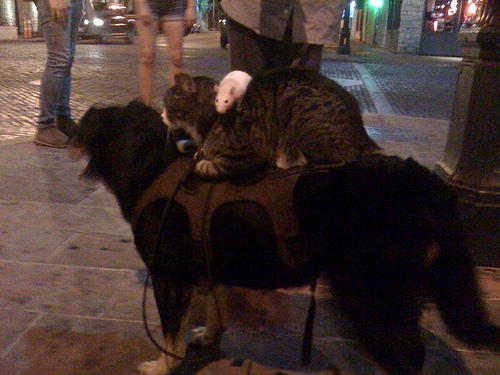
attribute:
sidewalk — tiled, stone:
[32, 269, 324, 374]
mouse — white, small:
[215, 70, 253, 113]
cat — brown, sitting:
[161, 82, 368, 172]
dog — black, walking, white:
[98, 128, 471, 309]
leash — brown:
[144, 175, 176, 348]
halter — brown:
[153, 177, 283, 215]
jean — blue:
[34, 27, 67, 119]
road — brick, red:
[345, 56, 451, 102]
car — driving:
[80, 4, 140, 40]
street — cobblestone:
[56, 35, 115, 89]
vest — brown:
[156, 179, 310, 247]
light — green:
[366, 3, 389, 17]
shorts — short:
[131, 2, 190, 23]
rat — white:
[192, 64, 244, 115]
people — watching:
[27, 8, 355, 71]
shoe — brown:
[38, 116, 76, 153]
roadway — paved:
[321, 61, 471, 111]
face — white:
[154, 90, 180, 134]